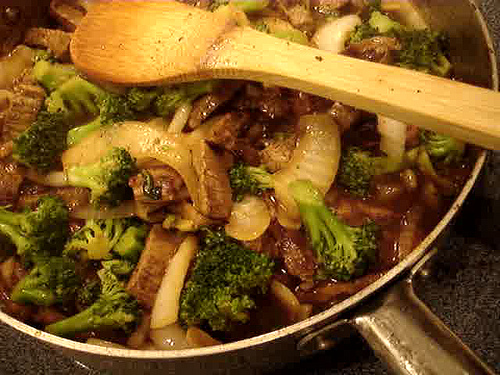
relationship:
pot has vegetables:
[1, 0, 492, 374] [1, 0, 468, 334]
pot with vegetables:
[1, 0, 492, 374] [1, 0, 468, 334]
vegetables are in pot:
[1, 0, 468, 334] [1, 0, 492, 374]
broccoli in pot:
[1, 198, 68, 265] [1, 0, 492, 374]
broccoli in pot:
[10, 114, 66, 173] [1, 0, 492, 374]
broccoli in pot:
[66, 149, 136, 204] [1, 0, 492, 374]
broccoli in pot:
[181, 228, 275, 334] [1, 0, 492, 374]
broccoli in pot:
[288, 179, 378, 283] [1, 0, 492, 374]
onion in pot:
[60, 120, 231, 219] [1, 0, 492, 374]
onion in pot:
[150, 234, 200, 330] [1, 0, 492, 374]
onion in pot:
[272, 114, 343, 228] [1, 0, 492, 374]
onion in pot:
[377, 114, 407, 163] [1, 0, 492, 374]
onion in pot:
[311, 15, 361, 54] [1, 0, 492, 374]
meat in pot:
[2, 78, 46, 147] [1, 0, 492, 374]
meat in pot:
[208, 111, 251, 150] [1, 0, 492, 374]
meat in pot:
[275, 227, 314, 279] [1, 0, 492, 374]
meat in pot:
[23, 26, 71, 57] [1, 0, 492, 374]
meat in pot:
[126, 223, 183, 310] [1, 0, 492, 374]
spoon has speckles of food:
[71, 3, 500, 154] [148, 7, 247, 77]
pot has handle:
[1, 0, 492, 374] [296, 248, 497, 375]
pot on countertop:
[1, 0, 492, 374] [2, 19, 499, 375]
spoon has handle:
[71, 3, 500, 154] [250, 28, 500, 154]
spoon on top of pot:
[71, 3, 500, 154] [1, 0, 492, 374]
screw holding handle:
[315, 336, 337, 354] [296, 248, 497, 375]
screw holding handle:
[417, 264, 435, 285] [296, 248, 497, 375]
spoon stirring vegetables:
[71, 3, 500, 154] [1, 0, 468, 334]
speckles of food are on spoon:
[148, 7, 247, 77] [71, 3, 500, 154]